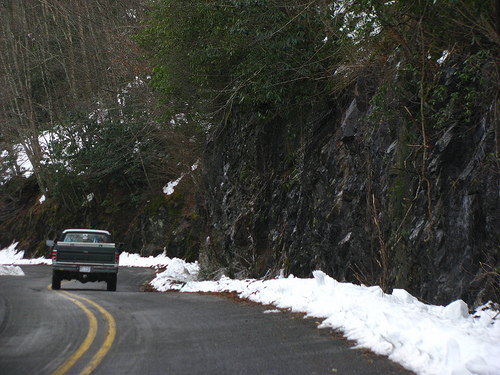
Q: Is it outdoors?
A: Yes, it is outdoors.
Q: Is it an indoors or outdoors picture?
A: It is outdoors.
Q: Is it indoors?
A: No, it is outdoors.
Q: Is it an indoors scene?
A: No, it is outdoors.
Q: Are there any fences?
A: No, there are no fences.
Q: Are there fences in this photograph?
A: No, there are no fences.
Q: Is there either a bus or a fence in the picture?
A: No, there are no fences or buses.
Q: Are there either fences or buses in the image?
A: No, there are no fences or buses.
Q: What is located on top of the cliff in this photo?
A: The forest is on top of the cliff.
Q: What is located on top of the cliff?
A: The forest is on top of the cliff.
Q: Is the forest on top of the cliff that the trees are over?
A: Yes, the forest is on top of the cliff.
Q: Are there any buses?
A: No, there are no buses.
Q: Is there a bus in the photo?
A: No, there are no buses.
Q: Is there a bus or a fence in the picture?
A: No, there are no buses or fences.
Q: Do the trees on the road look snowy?
A: No, the trees are rocky.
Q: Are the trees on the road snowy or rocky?
A: The trees are rocky.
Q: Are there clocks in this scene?
A: No, there are no clocks.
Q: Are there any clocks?
A: No, there are no clocks.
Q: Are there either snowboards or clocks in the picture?
A: No, there are no clocks or snowboards.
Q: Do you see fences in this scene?
A: No, there are no fences.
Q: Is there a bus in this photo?
A: No, there are no buses.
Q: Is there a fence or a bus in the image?
A: No, there are no buses or fences.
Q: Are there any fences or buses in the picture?
A: No, there are no buses or fences.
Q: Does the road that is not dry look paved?
A: Yes, the road is paved.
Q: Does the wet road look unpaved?
A: No, the road is paved.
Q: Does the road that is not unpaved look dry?
A: No, the road is wet.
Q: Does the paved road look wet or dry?
A: The road is wet.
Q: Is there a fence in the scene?
A: No, there are no fences.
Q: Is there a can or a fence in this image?
A: No, there are no fences or cans.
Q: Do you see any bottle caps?
A: No, there are no bottle caps.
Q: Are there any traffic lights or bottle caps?
A: No, there are no bottle caps or traffic lights.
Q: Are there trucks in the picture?
A: Yes, there is a truck.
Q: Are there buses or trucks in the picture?
A: Yes, there is a truck.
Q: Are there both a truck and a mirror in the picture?
A: Yes, there are both a truck and a mirror.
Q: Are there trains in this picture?
A: No, there are no trains.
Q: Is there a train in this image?
A: No, there are no trains.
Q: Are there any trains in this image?
A: No, there are no trains.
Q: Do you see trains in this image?
A: No, there are no trains.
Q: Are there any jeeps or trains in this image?
A: No, there are no trains or jeeps.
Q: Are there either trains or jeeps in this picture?
A: No, there are no trains or jeeps.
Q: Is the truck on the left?
A: Yes, the truck is on the left of the image.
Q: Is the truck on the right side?
A: No, the truck is on the left of the image.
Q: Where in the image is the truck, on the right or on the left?
A: The truck is on the left of the image.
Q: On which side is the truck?
A: The truck is on the left of the image.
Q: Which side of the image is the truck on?
A: The truck is on the left of the image.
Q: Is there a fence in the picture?
A: No, there are no fences.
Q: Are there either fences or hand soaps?
A: No, there are no fences or hand soaps.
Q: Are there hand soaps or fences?
A: No, there are no fences or hand soaps.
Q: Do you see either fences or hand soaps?
A: No, there are no fences or hand soaps.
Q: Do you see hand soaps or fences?
A: No, there are no fences or hand soaps.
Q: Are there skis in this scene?
A: No, there are no skis.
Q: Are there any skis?
A: No, there are no skis.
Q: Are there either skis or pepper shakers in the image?
A: No, there are no skis or pepper shakers.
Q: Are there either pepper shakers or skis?
A: No, there are no skis or pepper shakers.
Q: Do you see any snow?
A: Yes, there is snow.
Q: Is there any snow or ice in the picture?
A: Yes, there is snow.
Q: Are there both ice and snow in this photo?
A: No, there is snow but no ice.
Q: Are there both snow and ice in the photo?
A: No, there is snow but no ice.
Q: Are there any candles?
A: No, there are no candles.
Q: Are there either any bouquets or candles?
A: No, there are no candles or bouquets.